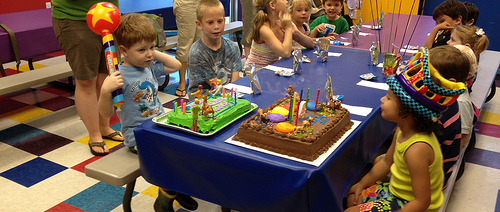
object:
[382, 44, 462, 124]
hat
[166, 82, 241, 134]
birthday cake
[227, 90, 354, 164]
cake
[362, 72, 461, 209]
child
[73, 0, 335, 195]
party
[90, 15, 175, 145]
boy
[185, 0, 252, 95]
boy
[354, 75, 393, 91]
paper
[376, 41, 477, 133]
hat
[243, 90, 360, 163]
cakes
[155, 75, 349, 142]
cakes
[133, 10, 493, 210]
table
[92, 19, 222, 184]
child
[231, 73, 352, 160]
cake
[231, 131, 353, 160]
icing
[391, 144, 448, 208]
shirt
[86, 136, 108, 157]
flip flop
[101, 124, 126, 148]
flip flop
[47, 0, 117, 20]
shirt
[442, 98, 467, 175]
shirt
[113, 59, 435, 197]
table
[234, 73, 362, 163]
cake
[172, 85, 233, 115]
figurines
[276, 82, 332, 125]
figurines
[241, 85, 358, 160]
birthday cake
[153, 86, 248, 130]
birthday cake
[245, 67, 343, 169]
cake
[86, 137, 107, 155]
sandle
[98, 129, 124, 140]
sandle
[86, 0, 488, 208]
children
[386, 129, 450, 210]
tank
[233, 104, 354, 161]
brown cake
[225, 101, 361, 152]
birtday cake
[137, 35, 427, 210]
table cloth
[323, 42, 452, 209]
child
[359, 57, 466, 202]
child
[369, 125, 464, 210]
shirt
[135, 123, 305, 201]
tablecloth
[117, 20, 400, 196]
table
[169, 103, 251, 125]
icing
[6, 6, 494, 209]
party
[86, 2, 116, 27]
design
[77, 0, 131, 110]
toy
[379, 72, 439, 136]
head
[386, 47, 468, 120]
crown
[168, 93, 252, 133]
cake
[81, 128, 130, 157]
sandals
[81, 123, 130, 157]
feet